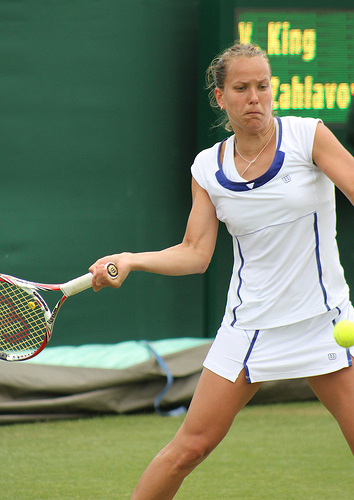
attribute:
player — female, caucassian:
[87, 44, 351, 499]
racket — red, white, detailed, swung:
[1, 258, 119, 365]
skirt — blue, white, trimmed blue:
[200, 296, 349, 384]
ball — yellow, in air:
[331, 318, 353, 348]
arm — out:
[122, 161, 218, 277]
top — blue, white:
[191, 116, 351, 334]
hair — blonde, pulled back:
[203, 43, 270, 135]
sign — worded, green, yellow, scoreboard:
[197, 1, 353, 141]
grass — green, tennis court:
[1, 400, 352, 499]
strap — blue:
[134, 339, 186, 419]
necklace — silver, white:
[231, 128, 278, 179]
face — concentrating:
[223, 55, 271, 131]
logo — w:
[327, 349, 339, 361]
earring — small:
[218, 102, 226, 111]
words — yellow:
[238, 20, 354, 113]